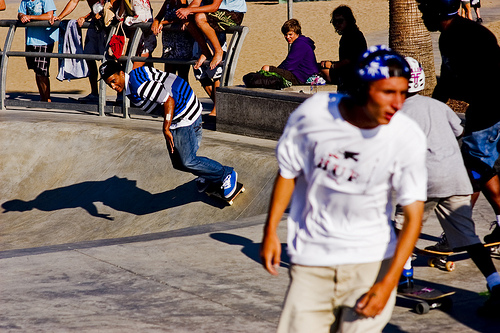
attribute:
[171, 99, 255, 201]
jeans — blue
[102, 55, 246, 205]
man — young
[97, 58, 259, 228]
man — young